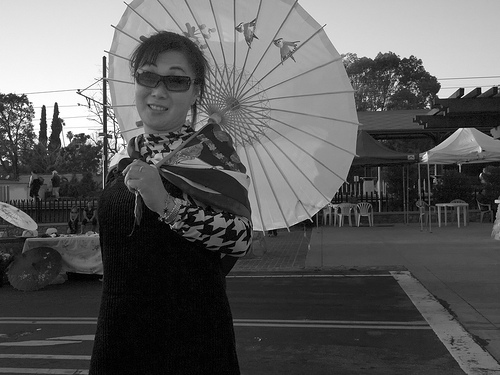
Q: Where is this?
A: This is at the street.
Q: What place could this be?
A: It is a street.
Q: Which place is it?
A: It is a street.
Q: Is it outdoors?
A: Yes, it is outdoors.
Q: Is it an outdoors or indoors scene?
A: It is outdoors.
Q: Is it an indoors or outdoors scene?
A: It is outdoors.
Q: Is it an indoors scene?
A: No, it is outdoors.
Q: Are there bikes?
A: No, there are no bikes.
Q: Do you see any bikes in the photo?
A: No, there are no bikes.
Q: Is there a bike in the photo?
A: No, there are no bikes.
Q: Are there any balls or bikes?
A: No, there are no bikes or balls.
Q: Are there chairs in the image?
A: Yes, there is a chair.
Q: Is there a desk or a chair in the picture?
A: Yes, there is a chair.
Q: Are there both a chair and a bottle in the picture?
A: No, there is a chair but no bottles.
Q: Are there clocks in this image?
A: No, there are no clocks.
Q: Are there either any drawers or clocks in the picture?
A: No, there are no clocks or drawers.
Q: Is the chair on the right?
A: Yes, the chair is on the right of the image.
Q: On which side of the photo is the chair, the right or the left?
A: The chair is on the right of the image.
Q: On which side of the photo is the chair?
A: The chair is on the right of the image.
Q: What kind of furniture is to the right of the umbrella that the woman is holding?
A: The piece of furniture is a chair.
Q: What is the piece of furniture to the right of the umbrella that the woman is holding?
A: The piece of furniture is a chair.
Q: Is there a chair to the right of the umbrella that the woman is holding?
A: Yes, there is a chair to the right of the umbrella.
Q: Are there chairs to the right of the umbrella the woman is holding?
A: Yes, there is a chair to the right of the umbrella.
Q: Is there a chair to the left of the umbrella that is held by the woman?
A: No, the chair is to the right of the umbrella.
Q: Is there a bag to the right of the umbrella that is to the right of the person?
A: No, there is a chair to the right of the umbrella.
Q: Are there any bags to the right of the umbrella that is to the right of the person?
A: No, there is a chair to the right of the umbrella.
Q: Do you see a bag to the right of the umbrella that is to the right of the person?
A: No, there is a chair to the right of the umbrella.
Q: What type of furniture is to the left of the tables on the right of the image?
A: The piece of furniture is a chair.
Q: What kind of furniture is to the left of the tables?
A: The piece of furniture is a chair.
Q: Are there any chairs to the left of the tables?
A: Yes, there is a chair to the left of the tables.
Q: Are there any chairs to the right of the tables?
A: No, the chair is to the left of the tables.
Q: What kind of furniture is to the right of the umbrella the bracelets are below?
A: The piece of furniture is a chair.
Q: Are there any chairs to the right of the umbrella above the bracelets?
A: Yes, there is a chair to the right of the umbrella.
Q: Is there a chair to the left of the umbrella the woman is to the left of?
A: No, the chair is to the right of the umbrella.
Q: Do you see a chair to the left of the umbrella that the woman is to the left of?
A: No, the chair is to the right of the umbrella.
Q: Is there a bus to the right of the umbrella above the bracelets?
A: No, there is a chair to the right of the umbrella.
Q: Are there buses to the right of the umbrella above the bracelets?
A: No, there is a chair to the right of the umbrella.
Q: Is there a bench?
A: No, there are no benches.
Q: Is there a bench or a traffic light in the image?
A: No, there are no benches or traffic lights.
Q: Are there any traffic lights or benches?
A: No, there are no benches or traffic lights.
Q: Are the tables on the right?
A: Yes, the tables are on the right of the image.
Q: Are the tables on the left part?
A: No, the tables are on the right of the image.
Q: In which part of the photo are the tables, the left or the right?
A: The tables are on the right of the image.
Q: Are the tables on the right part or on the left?
A: The tables are on the right of the image.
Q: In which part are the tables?
A: The tables are on the right of the image.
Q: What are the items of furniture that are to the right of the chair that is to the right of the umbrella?
A: The pieces of furniture are tables.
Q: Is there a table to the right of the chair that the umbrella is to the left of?
A: Yes, there are tables to the right of the chair.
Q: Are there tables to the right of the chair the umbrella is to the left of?
A: Yes, there are tables to the right of the chair.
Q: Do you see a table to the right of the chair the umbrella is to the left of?
A: Yes, there are tables to the right of the chair.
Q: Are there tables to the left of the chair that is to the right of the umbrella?
A: No, the tables are to the right of the chair.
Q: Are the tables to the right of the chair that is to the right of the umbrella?
A: Yes, the tables are to the right of the chair.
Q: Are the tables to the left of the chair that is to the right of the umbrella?
A: No, the tables are to the right of the chair.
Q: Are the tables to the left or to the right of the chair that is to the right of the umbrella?
A: The tables are to the right of the chair.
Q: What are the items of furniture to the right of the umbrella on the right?
A: The pieces of furniture are tables.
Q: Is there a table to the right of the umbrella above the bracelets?
A: Yes, there are tables to the right of the umbrella.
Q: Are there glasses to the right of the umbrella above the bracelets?
A: No, there are tables to the right of the umbrella.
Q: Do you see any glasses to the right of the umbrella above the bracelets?
A: No, there are tables to the right of the umbrella.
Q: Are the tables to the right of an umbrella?
A: Yes, the tables are to the right of an umbrella.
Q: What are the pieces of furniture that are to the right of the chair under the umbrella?
A: The pieces of furniture are tables.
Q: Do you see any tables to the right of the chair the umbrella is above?
A: Yes, there are tables to the right of the chair.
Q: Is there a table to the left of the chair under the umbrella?
A: No, the tables are to the right of the chair.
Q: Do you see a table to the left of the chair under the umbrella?
A: No, the tables are to the right of the chair.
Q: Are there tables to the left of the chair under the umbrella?
A: No, the tables are to the right of the chair.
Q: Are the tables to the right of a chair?
A: Yes, the tables are to the right of a chair.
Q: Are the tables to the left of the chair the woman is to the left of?
A: No, the tables are to the right of the chair.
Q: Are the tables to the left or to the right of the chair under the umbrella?
A: The tables are to the right of the chair.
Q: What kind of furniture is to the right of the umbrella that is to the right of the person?
A: The pieces of furniture are tables.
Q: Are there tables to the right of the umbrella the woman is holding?
A: Yes, there are tables to the right of the umbrella.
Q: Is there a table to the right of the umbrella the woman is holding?
A: Yes, there are tables to the right of the umbrella.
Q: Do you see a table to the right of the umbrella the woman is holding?
A: Yes, there are tables to the right of the umbrella.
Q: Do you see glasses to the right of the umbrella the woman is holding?
A: No, there are tables to the right of the umbrella.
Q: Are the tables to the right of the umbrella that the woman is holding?
A: Yes, the tables are to the right of the umbrella.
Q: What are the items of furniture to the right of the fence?
A: The pieces of furniture are tables.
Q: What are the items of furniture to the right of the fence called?
A: The pieces of furniture are tables.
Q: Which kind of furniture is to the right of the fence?
A: The pieces of furniture are tables.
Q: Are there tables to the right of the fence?
A: Yes, there are tables to the right of the fence.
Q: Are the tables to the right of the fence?
A: Yes, the tables are to the right of the fence.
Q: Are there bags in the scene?
A: No, there are no bags.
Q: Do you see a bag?
A: No, there are no bags.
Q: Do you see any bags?
A: No, there are no bags.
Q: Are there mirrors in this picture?
A: No, there are no mirrors.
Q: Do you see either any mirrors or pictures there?
A: No, there are no mirrors or pictures.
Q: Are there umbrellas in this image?
A: Yes, there is an umbrella.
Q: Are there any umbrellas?
A: Yes, there is an umbrella.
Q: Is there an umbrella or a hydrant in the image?
A: Yes, there is an umbrella.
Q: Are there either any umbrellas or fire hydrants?
A: Yes, there is an umbrella.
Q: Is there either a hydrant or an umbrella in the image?
A: Yes, there is an umbrella.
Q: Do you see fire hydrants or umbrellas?
A: Yes, there is an umbrella.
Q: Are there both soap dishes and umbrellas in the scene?
A: No, there is an umbrella but no soap dishes.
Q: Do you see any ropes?
A: No, there are no ropes.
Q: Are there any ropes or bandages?
A: No, there are no ropes or bandages.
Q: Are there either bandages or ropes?
A: No, there are no ropes or bandages.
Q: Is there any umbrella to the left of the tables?
A: Yes, there is an umbrella to the left of the tables.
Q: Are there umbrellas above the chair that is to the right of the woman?
A: Yes, there is an umbrella above the chair.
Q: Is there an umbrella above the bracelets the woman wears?
A: Yes, there is an umbrella above the bracelets.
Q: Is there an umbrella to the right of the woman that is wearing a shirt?
A: Yes, there is an umbrella to the right of the woman.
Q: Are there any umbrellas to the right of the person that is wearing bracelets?
A: Yes, there is an umbrella to the right of the woman.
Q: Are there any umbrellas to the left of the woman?
A: No, the umbrella is to the right of the woman.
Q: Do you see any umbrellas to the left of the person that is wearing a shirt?
A: No, the umbrella is to the right of the woman.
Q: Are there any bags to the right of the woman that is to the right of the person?
A: No, there is an umbrella to the right of the woman.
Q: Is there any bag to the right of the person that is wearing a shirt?
A: No, there is an umbrella to the right of the woman.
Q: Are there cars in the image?
A: No, there are no cars.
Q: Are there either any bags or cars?
A: No, there are no cars or bags.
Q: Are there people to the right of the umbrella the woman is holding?
A: No, the person is to the left of the umbrella.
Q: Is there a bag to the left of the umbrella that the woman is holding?
A: No, there is a person to the left of the umbrella.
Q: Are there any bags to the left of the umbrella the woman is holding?
A: No, there is a person to the left of the umbrella.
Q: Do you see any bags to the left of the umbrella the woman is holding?
A: No, there is a person to the left of the umbrella.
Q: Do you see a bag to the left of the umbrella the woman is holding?
A: No, there is a person to the left of the umbrella.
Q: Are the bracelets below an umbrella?
A: Yes, the bracelets are below an umbrella.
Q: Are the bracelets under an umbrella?
A: Yes, the bracelets are under an umbrella.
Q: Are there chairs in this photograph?
A: Yes, there is a chair.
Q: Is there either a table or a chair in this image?
A: Yes, there is a chair.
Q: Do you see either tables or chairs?
A: Yes, there is a chair.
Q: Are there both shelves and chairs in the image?
A: No, there is a chair but no shelves.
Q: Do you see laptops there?
A: No, there are no laptops.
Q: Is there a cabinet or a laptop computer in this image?
A: No, there are no laptops or cabinets.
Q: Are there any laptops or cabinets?
A: No, there are no laptops or cabinets.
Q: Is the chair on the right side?
A: Yes, the chair is on the right of the image.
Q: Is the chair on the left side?
A: No, the chair is on the right of the image.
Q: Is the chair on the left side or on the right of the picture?
A: The chair is on the right of the image.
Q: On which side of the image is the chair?
A: The chair is on the right of the image.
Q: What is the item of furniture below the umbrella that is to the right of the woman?
A: The piece of furniture is a chair.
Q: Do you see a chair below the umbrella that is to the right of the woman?
A: Yes, there is a chair below the umbrella.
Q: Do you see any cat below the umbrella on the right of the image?
A: No, there is a chair below the umbrella.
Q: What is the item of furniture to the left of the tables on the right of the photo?
A: The piece of furniture is a chair.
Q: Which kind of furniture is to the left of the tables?
A: The piece of furniture is a chair.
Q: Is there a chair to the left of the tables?
A: Yes, there is a chair to the left of the tables.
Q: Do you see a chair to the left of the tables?
A: Yes, there is a chair to the left of the tables.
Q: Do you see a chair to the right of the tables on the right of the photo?
A: No, the chair is to the left of the tables.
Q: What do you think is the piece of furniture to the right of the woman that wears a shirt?
A: The piece of furniture is a chair.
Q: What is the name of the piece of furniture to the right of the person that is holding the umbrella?
A: The piece of furniture is a chair.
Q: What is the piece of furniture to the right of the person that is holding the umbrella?
A: The piece of furniture is a chair.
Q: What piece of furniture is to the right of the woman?
A: The piece of furniture is a chair.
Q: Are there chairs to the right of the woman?
A: Yes, there is a chair to the right of the woman.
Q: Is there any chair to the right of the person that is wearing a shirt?
A: Yes, there is a chair to the right of the woman.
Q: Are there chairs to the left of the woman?
A: No, the chair is to the right of the woman.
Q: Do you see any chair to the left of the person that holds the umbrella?
A: No, the chair is to the right of the woman.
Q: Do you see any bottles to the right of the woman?
A: No, there is a chair to the right of the woman.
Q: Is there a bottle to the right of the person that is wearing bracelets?
A: No, there is a chair to the right of the woman.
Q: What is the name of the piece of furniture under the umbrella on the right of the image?
A: The piece of furniture is a chair.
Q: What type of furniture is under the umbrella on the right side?
A: The piece of furniture is a chair.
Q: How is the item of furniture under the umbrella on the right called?
A: The piece of furniture is a chair.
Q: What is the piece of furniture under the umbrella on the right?
A: The piece of furniture is a chair.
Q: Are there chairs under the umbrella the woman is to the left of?
A: Yes, there is a chair under the umbrella.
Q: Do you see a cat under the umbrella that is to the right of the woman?
A: No, there is a chair under the umbrella.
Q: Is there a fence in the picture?
A: Yes, there is a fence.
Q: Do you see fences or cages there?
A: Yes, there is a fence.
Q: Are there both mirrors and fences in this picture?
A: No, there is a fence but no mirrors.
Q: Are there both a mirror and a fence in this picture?
A: No, there is a fence but no mirrors.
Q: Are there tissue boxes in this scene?
A: No, there are no tissue boxes.